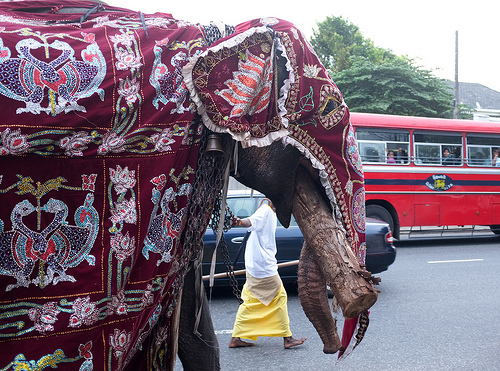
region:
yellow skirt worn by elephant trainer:
[236, 266, 311, 343]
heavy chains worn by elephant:
[201, 153, 223, 249]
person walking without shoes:
[260, 316, 317, 357]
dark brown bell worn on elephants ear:
[204, 110, 232, 185]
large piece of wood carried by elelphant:
[291, 158, 371, 330]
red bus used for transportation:
[352, 89, 493, 242]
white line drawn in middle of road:
[395, 231, 497, 268]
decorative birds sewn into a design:
[6, 199, 83, 289]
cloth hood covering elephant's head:
[211, 26, 424, 246]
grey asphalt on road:
[398, 289, 478, 347]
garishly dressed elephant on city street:
[1, 2, 379, 369]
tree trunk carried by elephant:
[285, 167, 389, 322]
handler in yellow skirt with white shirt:
[215, 180, 302, 366]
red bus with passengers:
[347, 105, 499, 255]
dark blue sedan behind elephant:
[195, 194, 393, 308]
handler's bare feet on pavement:
[229, 327, 310, 354]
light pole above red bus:
[439, 15, 474, 112]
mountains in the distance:
[432, 76, 499, 111]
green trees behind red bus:
[307, 11, 465, 118]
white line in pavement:
[417, 250, 488, 279]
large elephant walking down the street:
[1, 0, 383, 365]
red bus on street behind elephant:
[349, 109, 499, 234]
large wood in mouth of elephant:
[282, 178, 382, 316]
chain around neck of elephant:
[173, 156, 249, 302]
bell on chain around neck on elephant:
[203, 133, 223, 156]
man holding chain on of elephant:
[229, 196, 298, 348]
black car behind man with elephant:
[199, 188, 400, 292]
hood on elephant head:
[235, 16, 383, 263]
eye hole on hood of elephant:
[321, 91, 343, 119]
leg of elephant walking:
[178, 241, 221, 369]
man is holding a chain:
[192, 175, 312, 364]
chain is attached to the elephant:
[156, 117, 293, 310]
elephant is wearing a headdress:
[178, 4, 401, 337]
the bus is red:
[270, 65, 492, 260]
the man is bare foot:
[215, 307, 308, 358]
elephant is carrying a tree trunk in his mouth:
[257, 130, 402, 341]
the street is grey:
[392, 236, 488, 358]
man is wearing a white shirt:
[211, 196, 287, 288]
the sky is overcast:
[334, 0, 484, 97]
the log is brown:
[290, 173, 387, 325]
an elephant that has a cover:
[3, 1, 408, 366]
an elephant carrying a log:
[92, 3, 389, 365]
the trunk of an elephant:
[296, 248, 345, 362]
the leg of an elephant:
[175, 277, 227, 365]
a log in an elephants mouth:
[274, 171, 374, 334]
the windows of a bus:
[364, 126, 498, 169]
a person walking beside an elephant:
[226, 186, 323, 353]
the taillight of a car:
[381, 217, 396, 247]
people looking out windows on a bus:
[386, 144, 496, 169]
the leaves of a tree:
[341, 65, 403, 108]